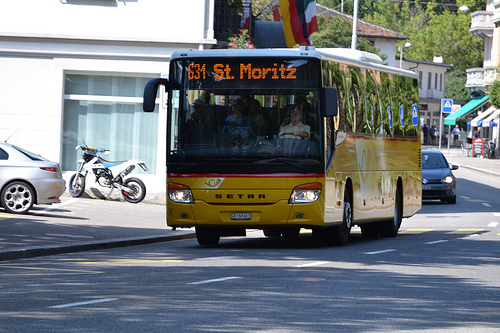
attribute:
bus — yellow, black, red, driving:
[139, 40, 430, 251]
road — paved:
[0, 147, 498, 332]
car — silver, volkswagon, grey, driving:
[421, 145, 461, 209]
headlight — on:
[441, 173, 456, 188]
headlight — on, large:
[282, 183, 322, 209]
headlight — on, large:
[162, 182, 197, 211]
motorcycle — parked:
[67, 137, 151, 206]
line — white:
[41, 190, 500, 324]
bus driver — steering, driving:
[277, 104, 314, 144]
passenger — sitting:
[223, 98, 251, 126]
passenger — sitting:
[244, 97, 268, 134]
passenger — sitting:
[188, 96, 211, 128]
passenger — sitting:
[289, 93, 315, 113]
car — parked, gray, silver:
[0, 134, 69, 220]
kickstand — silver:
[103, 184, 118, 201]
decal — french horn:
[196, 174, 229, 192]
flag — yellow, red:
[250, 1, 312, 49]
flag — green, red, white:
[299, 0, 325, 38]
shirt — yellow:
[274, 121, 314, 143]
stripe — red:
[165, 134, 424, 180]